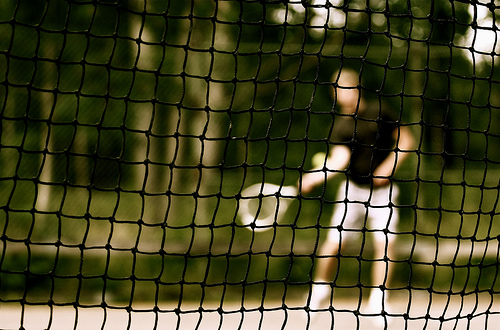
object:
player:
[296, 68, 414, 312]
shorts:
[327, 182, 399, 244]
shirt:
[326, 101, 404, 191]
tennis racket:
[236, 181, 299, 232]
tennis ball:
[311, 151, 327, 170]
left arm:
[371, 104, 414, 182]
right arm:
[298, 110, 351, 196]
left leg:
[364, 188, 399, 317]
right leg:
[306, 178, 365, 311]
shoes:
[305, 280, 335, 317]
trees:
[0, 10, 83, 216]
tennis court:
[0, 297, 500, 329]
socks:
[312, 277, 331, 290]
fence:
[0, 28, 499, 301]